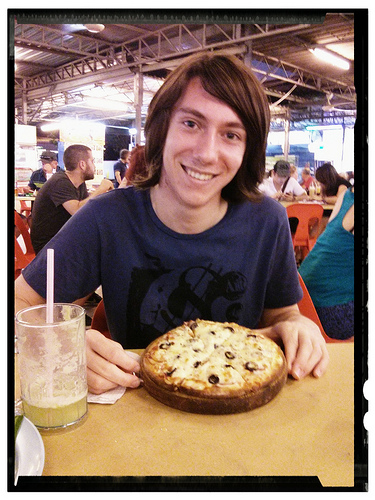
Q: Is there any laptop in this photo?
A: Yes, there is a laptop.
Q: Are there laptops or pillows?
A: Yes, there is a laptop.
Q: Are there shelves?
A: No, there are no shelves.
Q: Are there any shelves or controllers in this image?
A: No, there are no shelves or controllers.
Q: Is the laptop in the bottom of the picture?
A: Yes, the laptop is in the bottom of the image.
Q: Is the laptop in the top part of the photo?
A: No, the laptop is in the bottom of the image.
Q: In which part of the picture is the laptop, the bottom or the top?
A: The laptop is in the bottom of the image.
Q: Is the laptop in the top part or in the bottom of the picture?
A: The laptop is in the bottom of the image.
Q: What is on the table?
A: The laptop computer is on the table.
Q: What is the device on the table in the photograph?
A: The device is a laptop.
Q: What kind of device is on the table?
A: The device is a laptop.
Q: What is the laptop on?
A: The laptop is on the table.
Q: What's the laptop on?
A: The laptop is on the table.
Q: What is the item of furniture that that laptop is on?
A: The piece of furniture is a table.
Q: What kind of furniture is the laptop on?
A: The laptop is on the table.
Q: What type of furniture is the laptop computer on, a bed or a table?
A: The laptop computer is on a table.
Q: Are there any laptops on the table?
A: Yes, there is a laptop on the table.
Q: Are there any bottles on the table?
A: No, there is a laptop on the table.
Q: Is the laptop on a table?
A: Yes, the laptop is on a table.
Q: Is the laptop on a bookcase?
A: No, the laptop is on a table.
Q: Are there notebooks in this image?
A: No, there are no notebooks.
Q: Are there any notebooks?
A: No, there are no notebooks.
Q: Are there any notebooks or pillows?
A: No, there are no notebooks or pillows.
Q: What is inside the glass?
A: The liquid is inside the glass.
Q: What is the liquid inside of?
A: The liquid is inside the glass.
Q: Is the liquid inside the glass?
A: Yes, the liquid is inside the glass.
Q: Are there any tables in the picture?
A: Yes, there is a table.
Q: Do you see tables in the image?
A: Yes, there is a table.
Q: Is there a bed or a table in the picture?
A: Yes, there is a table.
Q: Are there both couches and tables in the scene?
A: No, there is a table but no couches.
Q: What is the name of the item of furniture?
A: The piece of furniture is a table.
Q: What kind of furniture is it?
A: The piece of furniture is a table.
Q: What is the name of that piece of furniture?
A: That is a table.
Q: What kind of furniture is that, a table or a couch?
A: That is a table.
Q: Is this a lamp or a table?
A: This is a table.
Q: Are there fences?
A: No, there are no fences.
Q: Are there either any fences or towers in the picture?
A: No, there are no fences or towers.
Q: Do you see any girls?
A: No, there are no girls.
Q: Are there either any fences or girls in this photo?
A: No, there are no girls or fences.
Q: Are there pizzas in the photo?
A: Yes, there is a pizza.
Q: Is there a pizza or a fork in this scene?
A: Yes, there is a pizza.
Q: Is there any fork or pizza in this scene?
A: Yes, there is a pizza.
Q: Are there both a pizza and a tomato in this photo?
A: No, there is a pizza but no tomatoes.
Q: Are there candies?
A: No, there are no candies.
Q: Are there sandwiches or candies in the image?
A: No, there are no candies or sandwiches.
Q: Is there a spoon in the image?
A: No, there are no spoons.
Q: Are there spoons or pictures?
A: No, there are no spoons or pictures.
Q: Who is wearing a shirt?
A: The man is wearing a shirt.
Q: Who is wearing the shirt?
A: The man is wearing a shirt.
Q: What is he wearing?
A: The man is wearing a shirt.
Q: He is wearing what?
A: The man is wearing a shirt.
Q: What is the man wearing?
A: The man is wearing a shirt.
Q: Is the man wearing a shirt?
A: Yes, the man is wearing a shirt.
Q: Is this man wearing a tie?
A: No, the man is wearing a shirt.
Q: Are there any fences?
A: No, there are no fences.